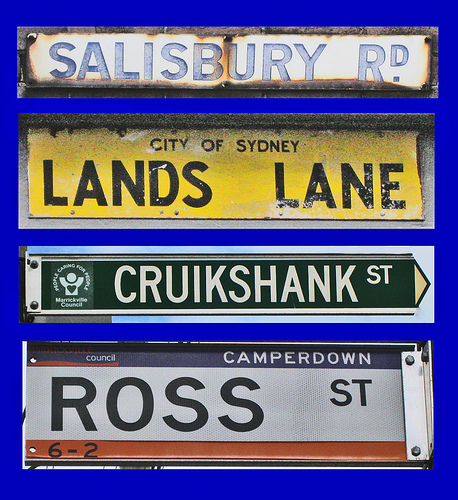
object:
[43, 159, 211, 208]
word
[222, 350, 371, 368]
word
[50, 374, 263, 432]
ross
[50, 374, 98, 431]
large letters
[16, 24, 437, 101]
worn sign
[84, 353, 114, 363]
word council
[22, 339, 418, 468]
sign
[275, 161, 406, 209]
word lane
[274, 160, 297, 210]
black letters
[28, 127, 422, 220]
yellow sign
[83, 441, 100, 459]
numbers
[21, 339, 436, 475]
bottom sign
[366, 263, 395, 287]
st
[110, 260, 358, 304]
word cruikshank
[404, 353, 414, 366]
silver screw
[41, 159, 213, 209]
lettering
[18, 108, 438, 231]
sign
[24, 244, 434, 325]
street sign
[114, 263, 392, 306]
cruikshank st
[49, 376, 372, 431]
ross st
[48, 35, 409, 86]
salisbury rd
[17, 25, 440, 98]
street sign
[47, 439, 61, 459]
numbering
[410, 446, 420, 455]
screw